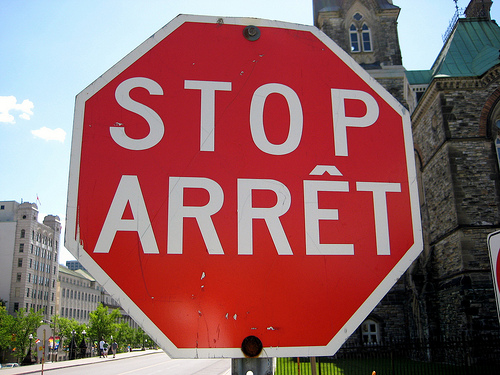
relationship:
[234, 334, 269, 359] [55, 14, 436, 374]
bolt holding up sign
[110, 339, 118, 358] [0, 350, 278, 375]
people are walking on ground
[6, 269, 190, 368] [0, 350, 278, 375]
trees lining ground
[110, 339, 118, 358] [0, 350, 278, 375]
people walking at ground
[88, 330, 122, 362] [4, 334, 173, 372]
people walking at sidewalk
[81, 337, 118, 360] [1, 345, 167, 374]
people walking at sidewalk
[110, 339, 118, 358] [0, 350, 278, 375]
people are in ground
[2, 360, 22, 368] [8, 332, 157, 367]
car in background